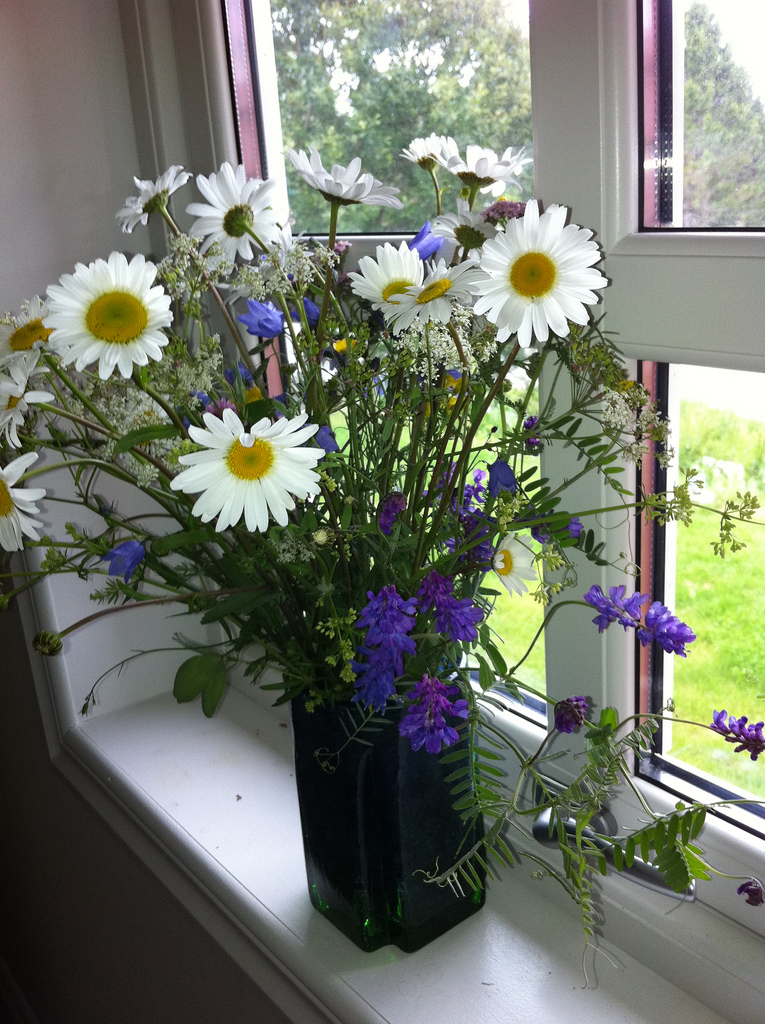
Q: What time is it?
A: Daytime.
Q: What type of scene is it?
A: Indoor.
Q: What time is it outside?
A: Daytime.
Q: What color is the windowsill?
A: White.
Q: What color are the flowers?
A: White and purple.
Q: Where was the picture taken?
A: On a window sill.